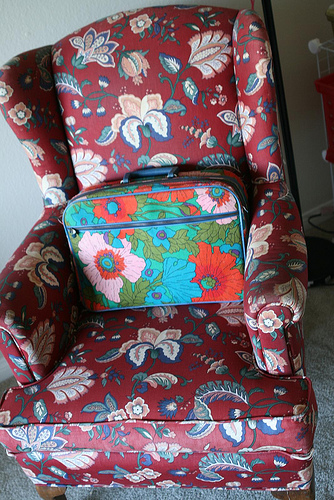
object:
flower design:
[187, 27, 233, 79]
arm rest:
[242, 182, 307, 377]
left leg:
[34, 480, 67, 497]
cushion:
[0, 299, 317, 489]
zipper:
[65, 210, 239, 235]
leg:
[272, 488, 317, 500]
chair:
[0, 0, 333, 500]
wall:
[0, 0, 334, 272]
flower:
[154, 327, 224, 390]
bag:
[61, 166, 251, 312]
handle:
[120, 165, 179, 182]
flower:
[100, 83, 179, 156]